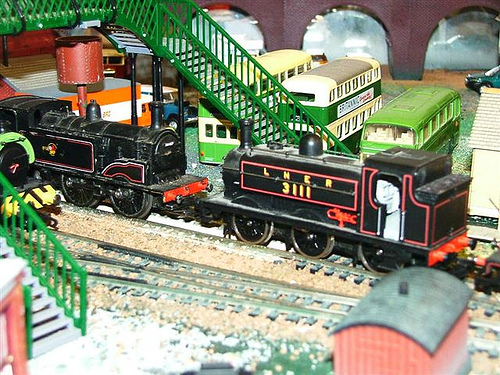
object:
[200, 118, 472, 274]
engine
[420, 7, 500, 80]
archways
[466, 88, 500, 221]
building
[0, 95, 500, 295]
train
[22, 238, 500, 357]
track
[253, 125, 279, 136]
stairs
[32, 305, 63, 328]
stairs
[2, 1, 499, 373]
train set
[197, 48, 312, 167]
bus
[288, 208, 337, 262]
wheel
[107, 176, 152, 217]
wheel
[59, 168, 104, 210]
wheel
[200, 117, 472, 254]
train car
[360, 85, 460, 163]
bus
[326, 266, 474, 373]
building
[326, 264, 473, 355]
roof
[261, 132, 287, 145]
stairs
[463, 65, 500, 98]
car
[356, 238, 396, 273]
wheel